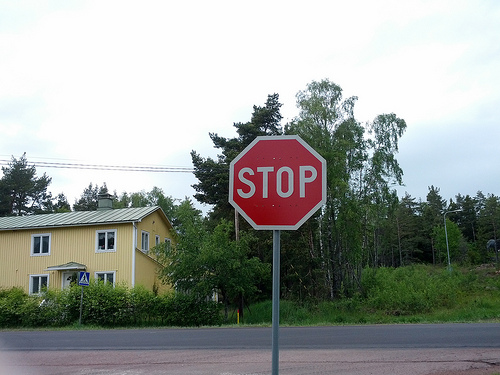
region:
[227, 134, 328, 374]
Stop sign on top of pole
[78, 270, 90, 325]
Blue and white sign on other side of street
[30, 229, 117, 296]
Windows on side of the house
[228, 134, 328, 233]
Red octagon with white lettering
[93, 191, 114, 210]
Chimney on top of roof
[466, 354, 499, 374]
Crack in concrete on side of road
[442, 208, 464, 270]
Unlit street light across the street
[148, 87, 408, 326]
Group of trees behind the stop sign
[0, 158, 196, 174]
Power lines close to the house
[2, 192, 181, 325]
Large yellow house across the street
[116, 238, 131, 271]
The house is yellow.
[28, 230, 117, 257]
The house has windows.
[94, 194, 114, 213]
The house has a chimney.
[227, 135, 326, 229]
The sign is a stop sign.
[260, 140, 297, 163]
The sign is red.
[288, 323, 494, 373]
The street is empty.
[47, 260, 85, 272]
An awning is on the house.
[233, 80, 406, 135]
Trees are next to the street.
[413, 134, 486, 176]
The sky is blue.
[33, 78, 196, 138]
The sky is partly cloudy.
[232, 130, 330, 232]
a red stop sign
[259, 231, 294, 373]
the pole of the stop sign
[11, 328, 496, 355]
the street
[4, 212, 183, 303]
a yellow house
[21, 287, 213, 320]
bushes in front of the house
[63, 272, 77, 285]
the front door of the house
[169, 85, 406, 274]
a large tree next to the hosue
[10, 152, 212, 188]
wires from a telephone pole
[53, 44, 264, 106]
white clouds in the sky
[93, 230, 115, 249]
a window of the house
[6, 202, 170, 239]
roof of a house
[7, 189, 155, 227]
ceiling of a house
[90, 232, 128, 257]
window of a house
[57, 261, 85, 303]
door of a house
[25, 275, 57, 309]
window of a house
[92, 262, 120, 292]
window of a house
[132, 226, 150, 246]
window of a house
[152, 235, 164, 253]
window of a house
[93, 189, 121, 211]
chimney of a house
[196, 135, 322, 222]
red and white stop sign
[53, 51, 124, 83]
white clouds in blue sky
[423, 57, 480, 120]
white clouds in blue sky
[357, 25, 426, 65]
white clouds in blue sky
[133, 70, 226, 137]
white clouds in blue sky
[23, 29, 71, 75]
white clouds in blue sky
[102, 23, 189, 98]
white clouds in blue sky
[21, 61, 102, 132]
white clouds in blue sky